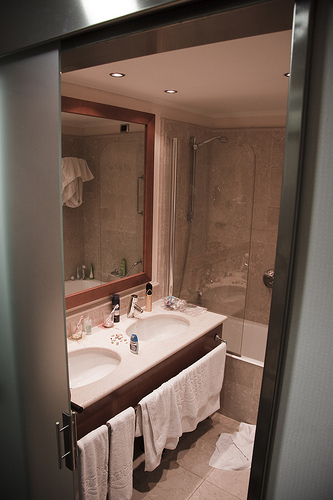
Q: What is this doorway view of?
A: A bathroom.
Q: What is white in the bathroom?
A: Towels.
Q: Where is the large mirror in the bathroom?
A: Wooden frame.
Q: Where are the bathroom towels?
A: Hanging over a bar.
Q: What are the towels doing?
A: Casting a shadow.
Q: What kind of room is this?
A: Bathroom.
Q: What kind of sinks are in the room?
A: Double sinks.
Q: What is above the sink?
A: Mirror.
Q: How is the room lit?
A: Recessed lighting.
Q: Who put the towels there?
A: The person who lives there.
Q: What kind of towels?
A: Big and small ones.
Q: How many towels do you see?
A: 6.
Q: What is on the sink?
A: A toothbrush.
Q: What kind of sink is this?
A: A dual sink.